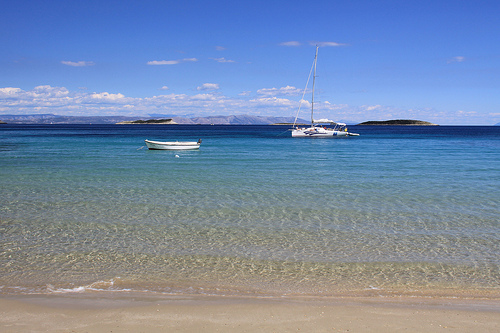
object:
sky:
[0, 0, 499, 126]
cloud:
[147, 59, 179, 65]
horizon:
[0, 114, 357, 127]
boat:
[145, 139, 203, 150]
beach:
[1, 279, 498, 332]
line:
[291, 43, 320, 128]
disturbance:
[174, 155, 179, 159]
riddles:
[1, 185, 499, 288]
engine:
[197, 138, 202, 144]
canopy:
[312, 118, 347, 131]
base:
[291, 41, 359, 137]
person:
[344, 128, 348, 132]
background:
[0, 0, 498, 126]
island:
[355, 119, 437, 126]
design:
[302, 129, 327, 136]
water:
[0, 262, 499, 296]